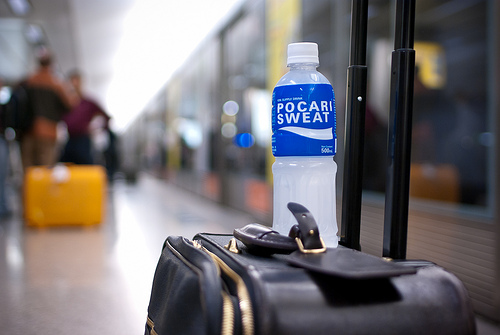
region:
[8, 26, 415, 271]
this is a train station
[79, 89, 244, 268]
this is a train platform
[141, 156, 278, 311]
this is train stop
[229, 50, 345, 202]
this is a water bottle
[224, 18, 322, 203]
the bottle is made of plastic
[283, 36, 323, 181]
the bottle is white and blue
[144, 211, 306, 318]
this is a suitcase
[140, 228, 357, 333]
the suitcase is leather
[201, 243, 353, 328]
the suitcase is black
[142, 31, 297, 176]
this is a metro train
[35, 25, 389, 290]
this is a train stop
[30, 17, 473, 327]
this is public transit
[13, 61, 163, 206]
the background is blurry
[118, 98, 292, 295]
the foreground is in focus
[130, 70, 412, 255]
this is a drink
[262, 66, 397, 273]
the drink is in a bottle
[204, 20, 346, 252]
the bottle is plastic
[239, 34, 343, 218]
the bottle is blue and white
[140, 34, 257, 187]
the train is made of steel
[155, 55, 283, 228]
the train is silver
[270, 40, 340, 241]
water bottle with blue label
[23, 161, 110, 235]
yellow suitcase sitting in airport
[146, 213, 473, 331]
black luggage in foreground with water bottle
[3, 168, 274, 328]
shiny white hallway in airport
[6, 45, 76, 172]
man with back to camera with orange and black jacket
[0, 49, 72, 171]
man carrying black backpack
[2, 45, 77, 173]
balding man standing wearing khaki pants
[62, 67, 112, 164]
person standing wearing maroon shirt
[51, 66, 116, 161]
man wearing black pants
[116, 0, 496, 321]
glass walls in airport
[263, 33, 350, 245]
clear bottle of water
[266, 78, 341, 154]
blue and white label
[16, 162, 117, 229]
yellow suitcase sitting on the ground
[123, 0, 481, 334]
suitcase with the handle up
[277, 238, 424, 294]
tag on top of the suitcase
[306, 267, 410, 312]
shadow on the suitcase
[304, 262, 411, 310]
shadow from the tag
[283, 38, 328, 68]
white cap on top of the water bottle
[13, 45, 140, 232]
two people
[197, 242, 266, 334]
gold zippers on the bag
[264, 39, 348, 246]
a water bottle full of water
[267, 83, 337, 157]
a blue label with white writing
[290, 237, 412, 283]
a black luggage tag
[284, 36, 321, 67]
white water bottle cap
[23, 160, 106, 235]
yellow luggage on the ground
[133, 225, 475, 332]
black suitcase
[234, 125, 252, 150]
bright blue light reflection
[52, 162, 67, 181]
white luggage tag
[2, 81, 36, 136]
black backpack on a mans shoulder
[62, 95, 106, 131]
purple shirt